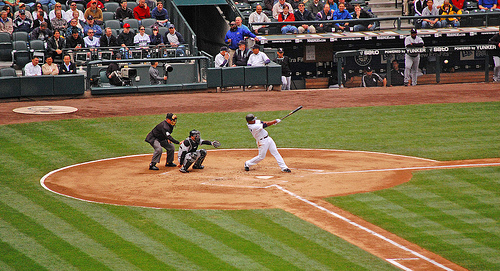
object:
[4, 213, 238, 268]
stripes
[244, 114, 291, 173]
batter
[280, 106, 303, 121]
bat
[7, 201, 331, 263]
grass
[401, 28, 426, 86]
person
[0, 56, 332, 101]
fence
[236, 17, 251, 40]
people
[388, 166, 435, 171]
line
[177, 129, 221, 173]
catcher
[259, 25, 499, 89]
dugout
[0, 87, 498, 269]
field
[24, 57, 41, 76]
people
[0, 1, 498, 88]
stands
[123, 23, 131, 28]
hat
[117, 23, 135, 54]
man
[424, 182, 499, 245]
grass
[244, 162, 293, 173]
shoes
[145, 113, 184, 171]
umpire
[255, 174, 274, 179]
homeplate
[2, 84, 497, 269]
ground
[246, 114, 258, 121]
helmets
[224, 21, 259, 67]
men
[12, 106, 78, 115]
plate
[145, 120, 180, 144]
black shirt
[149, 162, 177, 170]
shoes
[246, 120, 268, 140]
shirts